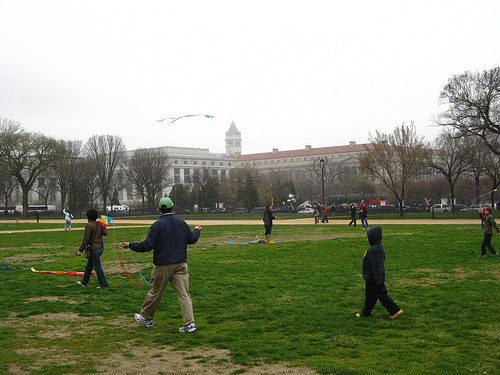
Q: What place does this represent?
A: It represents the field.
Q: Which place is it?
A: It is a field.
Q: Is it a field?
A: Yes, it is a field.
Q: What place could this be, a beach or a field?
A: It is a field.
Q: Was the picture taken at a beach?
A: No, the picture was taken in a field.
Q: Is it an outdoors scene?
A: Yes, it is outdoors.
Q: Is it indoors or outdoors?
A: It is outdoors.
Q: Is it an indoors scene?
A: No, it is outdoors.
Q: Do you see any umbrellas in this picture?
A: No, there are no umbrellas.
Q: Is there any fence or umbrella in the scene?
A: No, there are no umbrellas or fences.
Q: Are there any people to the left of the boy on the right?
A: Yes, there are people to the left of the boy.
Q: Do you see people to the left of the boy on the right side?
A: Yes, there are people to the left of the boy.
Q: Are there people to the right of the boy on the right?
A: No, the people are to the left of the boy.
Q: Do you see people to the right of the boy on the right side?
A: No, the people are to the left of the boy.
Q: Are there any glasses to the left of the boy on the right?
A: No, there are people to the left of the boy.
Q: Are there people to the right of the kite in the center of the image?
A: Yes, there are people to the right of the kite.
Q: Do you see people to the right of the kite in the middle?
A: Yes, there are people to the right of the kite.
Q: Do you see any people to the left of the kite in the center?
A: No, the people are to the right of the kite.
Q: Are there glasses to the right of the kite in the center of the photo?
A: No, there are people to the right of the kite.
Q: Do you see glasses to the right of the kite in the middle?
A: No, there are people to the right of the kite.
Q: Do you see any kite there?
A: Yes, there is a kite.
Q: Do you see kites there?
A: Yes, there is a kite.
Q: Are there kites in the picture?
A: Yes, there is a kite.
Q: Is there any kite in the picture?
A: Yes, there is a kite.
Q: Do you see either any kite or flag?
A: Yes, there is a kite.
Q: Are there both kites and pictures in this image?
A: No, there is a kite but no pictures.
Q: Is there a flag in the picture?
A: No, there are no flags.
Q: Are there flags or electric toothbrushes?
A: No, there are no flags or electric toothbrushes.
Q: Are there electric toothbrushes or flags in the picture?
A: No, there are no flags or electric toothbrushes.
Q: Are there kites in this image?
A: Yes, there is a kite.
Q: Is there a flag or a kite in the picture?
A: Yes, there is a kite.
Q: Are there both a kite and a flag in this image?
A: No, there is a kite but no flags.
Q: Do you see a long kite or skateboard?
A: Yes, there is a long kite.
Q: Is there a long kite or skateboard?
A: Yes, there is a long kite.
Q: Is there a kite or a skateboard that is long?
A: Yes, the kite is long.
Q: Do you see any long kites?
A: Yes, there is a long kite.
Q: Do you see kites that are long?
A: Yes, there is a kite that is long.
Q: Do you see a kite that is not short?
A: Yes, there is a long kite.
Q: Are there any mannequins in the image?
A: No, there are no mannequins.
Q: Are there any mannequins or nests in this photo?
A: No, there are no mannequins or nests.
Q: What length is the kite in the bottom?
A: The kite is long.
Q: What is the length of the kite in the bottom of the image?
A: The kite is long.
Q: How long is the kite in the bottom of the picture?
A: The kite is long.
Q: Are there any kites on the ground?
A: Yes, there is a kite on the ground.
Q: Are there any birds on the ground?
A: No, there is a kite on the ground.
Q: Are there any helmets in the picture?
A: No, there are no helmets.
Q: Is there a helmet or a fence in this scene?
A: No, there are no helmets or fences.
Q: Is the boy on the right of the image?
A: Yes, the boy is on the right of the image.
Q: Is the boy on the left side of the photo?
A: No, the boy is on the right of the image.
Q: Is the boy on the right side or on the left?
A: The boy is on the right of the image.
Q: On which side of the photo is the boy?
A: The boy is on the right of the image.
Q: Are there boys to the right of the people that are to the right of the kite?
A: Yes, there is a boy to the right of the people.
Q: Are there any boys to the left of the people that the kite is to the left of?
A: No, the boy is to the right of the people.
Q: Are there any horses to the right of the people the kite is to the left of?
A: No, there is a boy to the right of the people.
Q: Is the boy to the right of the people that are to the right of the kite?
A: Yes, the boy is to the right of the people.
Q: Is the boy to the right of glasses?
A: No, the boy is to the right of the people.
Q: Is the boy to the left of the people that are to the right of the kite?
A: No, the boy is to the right of the people.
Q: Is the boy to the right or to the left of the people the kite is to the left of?
A: The boy is to the right of the people.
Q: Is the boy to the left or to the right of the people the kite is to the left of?
A: The boy is to the right of the people.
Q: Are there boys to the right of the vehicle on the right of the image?
A: Yes, there is a boy to the right of the vehicle.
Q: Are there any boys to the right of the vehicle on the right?
A: Yes, there is a boy to the right of the vehicle.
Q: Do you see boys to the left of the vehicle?
A: No, the boy is to the right of the vehicle.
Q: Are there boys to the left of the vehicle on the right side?
A: No, the boy is to the right of the vehicle.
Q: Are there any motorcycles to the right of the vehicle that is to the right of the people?
A: No, there is a boy to the right of the vehicle.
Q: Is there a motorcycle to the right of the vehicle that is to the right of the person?
A: No, there is a boy to the right of the vehicle.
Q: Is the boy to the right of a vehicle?
A: Yes, the boy is to the right of a vehicle.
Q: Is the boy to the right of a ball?
A: No, the boy is to the right of a vehicle.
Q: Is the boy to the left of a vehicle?
A: No, the boy is to the right of a vehicle.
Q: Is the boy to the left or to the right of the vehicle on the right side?
A: The boy is to the right of the vehicle.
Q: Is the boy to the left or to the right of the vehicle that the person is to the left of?
A: The boy is to the right of the vehicle.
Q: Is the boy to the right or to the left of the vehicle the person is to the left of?
A: The boy is to the right of the vehicle.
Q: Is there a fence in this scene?
A: No, there are no fences.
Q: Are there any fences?
A: No, there are no fences.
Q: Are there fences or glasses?
A: No, there are no fences or glasses.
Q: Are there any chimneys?
A: No, there are no chimneys.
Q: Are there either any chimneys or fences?
A: No, there are no chimneys or fences.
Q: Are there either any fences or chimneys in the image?
A: No, there are no chimneys or fences.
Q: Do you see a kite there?
A: Yes, there is a kite.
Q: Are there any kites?
A: Yes, there is a kite.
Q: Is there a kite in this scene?
A: Yes, there is a kite.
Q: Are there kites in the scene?
A: Yes, there is a kite.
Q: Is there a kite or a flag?
A: Yes, there is a kite.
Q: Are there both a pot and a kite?
A: No, there is a kite but no pots.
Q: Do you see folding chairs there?
A: No, there are no folding chairs.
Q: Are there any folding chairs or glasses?
A: No, there are no folding chairs or glasses.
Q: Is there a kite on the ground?
A: Yes, there is a kite on the ground.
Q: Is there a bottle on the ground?
A: No, there is a kite on the ground.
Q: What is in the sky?
A: The kite is in the sky.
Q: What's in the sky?
A: The kite is in the sky.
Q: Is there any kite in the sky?
A: Yes, there is a kite in the sky.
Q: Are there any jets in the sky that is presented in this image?
A: No, there is a kite in the sky.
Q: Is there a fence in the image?
A: No, there are no fences.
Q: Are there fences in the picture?
A: No, there are no fences.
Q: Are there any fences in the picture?
A: No, there are no fences.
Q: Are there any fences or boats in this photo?
A: No, there are no fences or boats.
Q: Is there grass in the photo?
A: Yes, there is grass.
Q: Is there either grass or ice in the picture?
A: Yes, there is grass.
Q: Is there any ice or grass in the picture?
A: Yes, there is grass.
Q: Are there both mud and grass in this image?
A: No, there is grass but no mud.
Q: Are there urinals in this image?
A: No, there are no urinals.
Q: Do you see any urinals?
A: No, there are no urinals.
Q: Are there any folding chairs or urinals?
A: No, there are no urinals or folding chairs.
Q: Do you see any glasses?
A: No, there are no glasses.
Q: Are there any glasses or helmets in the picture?
A: No, there are no glasses or helmets.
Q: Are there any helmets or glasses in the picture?
A: No, there are no glasses or helmets.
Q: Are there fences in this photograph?
A: No, there are no fences.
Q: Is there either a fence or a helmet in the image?
A: No, there are no fences or helmets.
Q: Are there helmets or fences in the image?
A: No, there are no fences or helmets.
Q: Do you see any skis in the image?
A: No, there are no skis.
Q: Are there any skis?
A: No, there are no skis.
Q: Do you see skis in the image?
A: No, there are no skis.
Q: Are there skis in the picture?
A: No, there are no skis.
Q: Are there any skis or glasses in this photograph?
A: No, there are no skis or glasses.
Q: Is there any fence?
A: No, there are no fences.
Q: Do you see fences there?
A: No, there are no fences.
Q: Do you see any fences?
A: No, there are no fences.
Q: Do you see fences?
A: No, there are no fences.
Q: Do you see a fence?
A: No, there are no fences.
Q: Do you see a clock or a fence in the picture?
A: No, there are no fences or clocks.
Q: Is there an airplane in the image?
A: No, there are no airplanes.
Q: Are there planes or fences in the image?
A: No, there are no planes or fences.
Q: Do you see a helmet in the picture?
A: No, there are no helmets.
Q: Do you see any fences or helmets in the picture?
A: No, there are no helmets or fences.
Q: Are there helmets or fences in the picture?
A: No, there are no helmets or fences.